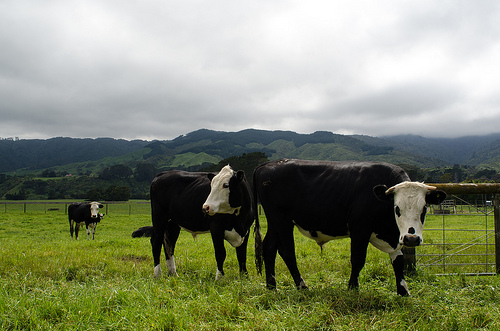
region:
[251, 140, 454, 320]
one cow standing in the pasture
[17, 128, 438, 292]
cows in the pasture getting ready to graze in the grass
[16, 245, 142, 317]
long green grass in the pasture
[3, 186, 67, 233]
a fence surrounding the pasture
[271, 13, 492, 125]
many clouds in the sky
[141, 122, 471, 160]
hilly mountaintop filled with trees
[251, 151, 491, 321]
a cow standing next to a fence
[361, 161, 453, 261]
A cow with a white head and black eyes, nose and ears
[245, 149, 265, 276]
A cows tail which is not wagging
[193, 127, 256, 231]
A cow looking to his right side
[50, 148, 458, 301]
Cows in a farm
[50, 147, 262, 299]
Cows have white heads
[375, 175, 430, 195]
Horn of bull is white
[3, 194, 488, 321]
Field has green grass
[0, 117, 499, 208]
Trees in the back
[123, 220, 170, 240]
A cow is lying in the grass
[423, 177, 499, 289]
Fence is wired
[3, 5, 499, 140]
Sky is cloudy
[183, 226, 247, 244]
Underbelly of cow id white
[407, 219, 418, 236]
Black spot on front of head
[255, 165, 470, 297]
Cow in the front looking at the camera.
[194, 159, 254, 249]
Cow looking away from the camera.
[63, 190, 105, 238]
Cow in the background looking at the camera.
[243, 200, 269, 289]
Tail of the cow looking at the camera.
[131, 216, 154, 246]
Animal lying down in the picture.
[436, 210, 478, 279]
Gate of the pasture fence.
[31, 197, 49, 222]
Fence in the pasture.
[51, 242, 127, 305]
Pasture where the cows are.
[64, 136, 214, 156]
Mountains in the background.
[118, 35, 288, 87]
Clouds in the sky.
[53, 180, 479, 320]
the cows are black and white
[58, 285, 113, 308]
the grass is green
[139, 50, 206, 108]
the sky is covered by clouds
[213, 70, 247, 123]
clouds are grey in color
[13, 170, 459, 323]
this is in a farm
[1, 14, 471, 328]
it is cloudy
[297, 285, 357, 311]
shadow is cast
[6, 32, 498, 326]
it is a daytime scene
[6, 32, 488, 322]
it is an outdoor scene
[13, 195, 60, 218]
the area is fenced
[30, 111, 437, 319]
a group of cows in a grassy field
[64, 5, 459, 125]
sky is cloudy and overcast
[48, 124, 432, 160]
forest covered hills in the back ground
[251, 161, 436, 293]
large spotted black and white cow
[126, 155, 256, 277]
spotted black and white cow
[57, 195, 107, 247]
black and white cow in the background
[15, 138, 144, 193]
trees cover the hillside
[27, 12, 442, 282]
cows out in the field on a gloomy day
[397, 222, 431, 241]
cow has a spot above its nose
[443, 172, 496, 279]
part of a fence